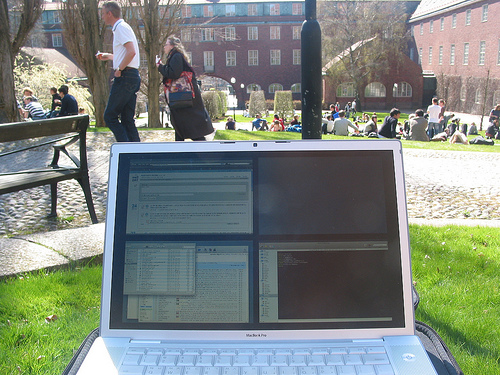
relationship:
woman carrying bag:
[152, 34, 217, 139] [166, 90, 196, 110]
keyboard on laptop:
[119, 345, 396, 373] [69, 138, 439, 373]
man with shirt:
[94, 0, 141, 143] [108, 19, 140, 72]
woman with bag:
[152, 34, 217, 139] [169, 91, 193, 108]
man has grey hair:
[94, 0, 141, 143] [98, 4, 119, 17]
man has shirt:
[94, 0, 141, 143] [94, 16, 161, 81]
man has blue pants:
[94, 2, 142, 147] [102, 66, 148, 145]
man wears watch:
[94, 0, 141, 143] [118, 65, 130, 71]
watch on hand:
[118, 65, 130, 71] [113, 67, 126, 83]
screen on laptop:
[108, 148, 405, 328] [69, 138, 439, 373]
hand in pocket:
[111, 67, 125, 79] [112, 74, 126, 88]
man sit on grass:
[94, 0, 141, 143] [214, 110, 497, 155]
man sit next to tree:
[94, 0, 141, 143] [3, 12, 185, 108]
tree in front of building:
[313, 0, 402, 113] [309, 37, 456, 102]